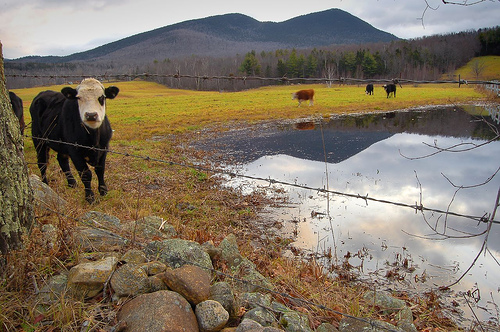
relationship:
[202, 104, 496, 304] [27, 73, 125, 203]
pond near cow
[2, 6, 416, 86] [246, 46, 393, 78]
hills with trees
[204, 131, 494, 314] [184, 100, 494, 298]
reflection of pond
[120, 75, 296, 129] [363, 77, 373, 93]
grass for cow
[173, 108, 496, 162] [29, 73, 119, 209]
pond for cow